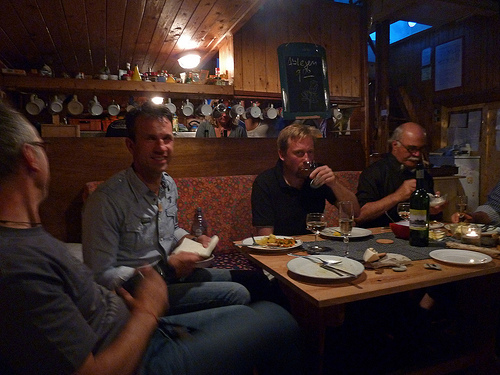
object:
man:
[251, 124, 359, 234]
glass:
[298, 159, 324, 188]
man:
[82, 102, 253, 309]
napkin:
[174, 234, 219, 257]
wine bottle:
[409, 164, 432, 247]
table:
[230, 219, 500, 374]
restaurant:
[2, 0, 500, 374]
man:
[355, 122, 449, 228]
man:
[0, 95, 306, 374]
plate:
[287, 254, 363, 279]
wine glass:
[306, 212, 327, 252]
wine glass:
[397, 200, 411, 222]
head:
[123, 102, 177, 174]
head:
[390, 123, 428, 166]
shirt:
[80, 163, 187, 279]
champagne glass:
[339, 198, 355, 258]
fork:
[290, 247, 342, 268]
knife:
[317, 260, 356, 278]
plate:
[239, 232, 304, 250]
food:
[260, 235, 297, 248]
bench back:
[83, 169, 363, 252]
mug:
[197, 96, 212, 117]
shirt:
[2, 221, 139, 370]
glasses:
[396, 139, 428, 153]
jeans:
[154, 264, 254, 311]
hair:
[124, 101, 173, 140]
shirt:
[250, 158, 338, 235]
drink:
[297, 160, 317, 176]